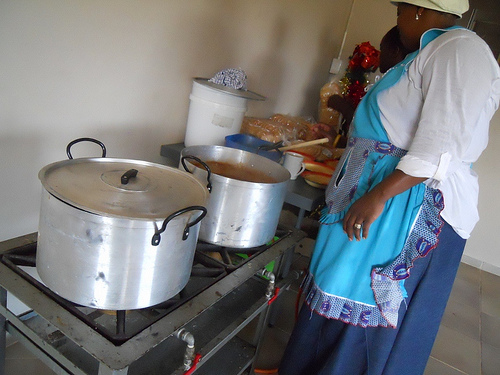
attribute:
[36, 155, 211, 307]
pot — real, steel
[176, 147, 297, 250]
pot — real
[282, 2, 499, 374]
person — real, cooking, working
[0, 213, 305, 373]
stove — real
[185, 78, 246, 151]
bucket — white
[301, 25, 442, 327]
apron — blue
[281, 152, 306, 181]
cup — white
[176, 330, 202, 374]
line — metal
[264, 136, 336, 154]
utensil — wood